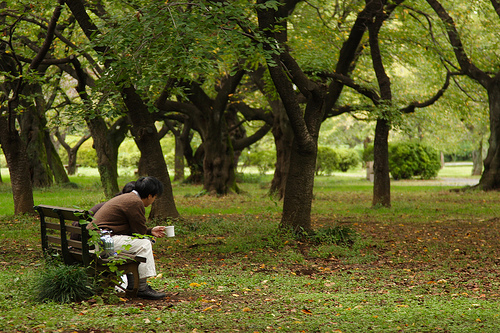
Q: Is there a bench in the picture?
A: Yes, there is a bench.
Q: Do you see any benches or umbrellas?
A: Yes, there is a bench.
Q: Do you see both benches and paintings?
A: No, there is a bench but no paintings.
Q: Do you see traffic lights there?
A: No, there are no traffic lights.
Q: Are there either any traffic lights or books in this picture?
A: No, there are no traffic lights or books.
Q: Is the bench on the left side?
A: Yes, the bench is on the left of the image.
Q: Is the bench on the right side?
A: No, the bench is on the left of the image.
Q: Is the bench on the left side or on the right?
A: The bench is on the left of the image.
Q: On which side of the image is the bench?
A: The bench is on the left of the image.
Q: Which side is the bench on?
A: The bench is on the left of the image.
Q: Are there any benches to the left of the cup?
A: Yes, there is a bench to the left of the cup.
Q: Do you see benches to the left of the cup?
A: Yes, there is a bench to the left of the cup.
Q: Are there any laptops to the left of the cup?
A: No, there is a bench to the left of the cup.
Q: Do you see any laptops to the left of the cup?
A: No, there is a bench to the left of the cup.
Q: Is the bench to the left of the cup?
A: Yes, the bench is to the left of the cup.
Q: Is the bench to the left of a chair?
A: No, the bench is to the left of the cup.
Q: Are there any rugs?
A: No, there are no rugs.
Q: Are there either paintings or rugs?
A: No, there are no rugs or paintings.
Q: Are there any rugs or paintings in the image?
A: No, there are no rugs or paintings.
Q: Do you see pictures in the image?
A: No, there are no pictures.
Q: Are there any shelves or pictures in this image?
A: No, there are no pictures or shelves.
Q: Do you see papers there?
A: No, there are no papers.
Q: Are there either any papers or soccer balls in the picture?
A: No, there are no papers or soccer balls.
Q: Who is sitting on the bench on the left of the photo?
A: The couple is sitting on the bench.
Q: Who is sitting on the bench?
A: The couple is sitting on the bench.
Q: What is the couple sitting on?
A: The couple is sitting on the bench.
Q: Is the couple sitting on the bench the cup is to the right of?
A: Yes, the couple is sitting on the bench.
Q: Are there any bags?
A: No, there are no bags.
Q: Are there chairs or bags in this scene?
A: No, there are no bags or chairs.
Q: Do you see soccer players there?
A: No, there are no soccer players.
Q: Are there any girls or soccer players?
A: No, there are no soccer players or girls.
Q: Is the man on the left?
A: Yes, the man is on the left of the image.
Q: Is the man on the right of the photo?
A: No, the man is on the left of the image.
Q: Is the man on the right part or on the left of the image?
A: The man is on the left of the image.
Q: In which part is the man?
A: The man is on the left of the image.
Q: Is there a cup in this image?
A: Yes, there is a cup.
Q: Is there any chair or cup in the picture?
A: Yes, there is a cup.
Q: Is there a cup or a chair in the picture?
A: Yes, there is a cup.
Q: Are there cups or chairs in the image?
A: Yes, there is a cup.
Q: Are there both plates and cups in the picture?
A: No, there is a cup but no plates.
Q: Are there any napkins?
A: No, there are no napkins.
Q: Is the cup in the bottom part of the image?
A: Yes, the cup is in the bottom of the image.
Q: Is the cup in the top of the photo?
A: No, the cup is in the bottom of the image.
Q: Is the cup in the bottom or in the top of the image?
A: The cup is in the bottom of the image.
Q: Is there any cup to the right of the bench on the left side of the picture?
A: Yes, there is a cup to the right of the bench.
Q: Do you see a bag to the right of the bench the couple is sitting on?
A: No, there is a cup to the right of the bench.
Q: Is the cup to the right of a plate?
A: No, the cup is to the right of the bench.